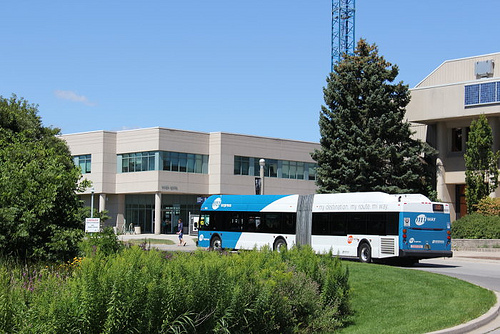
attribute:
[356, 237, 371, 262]
tire — black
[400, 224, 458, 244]
lights — red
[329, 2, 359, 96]
tower — black, metal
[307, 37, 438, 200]
tree — tall, evergreen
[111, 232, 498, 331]
street — circular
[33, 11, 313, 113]
sky — blue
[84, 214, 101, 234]
white sign — informational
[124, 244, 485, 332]
grass — green, short